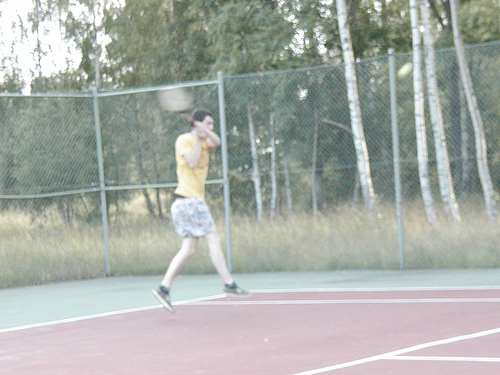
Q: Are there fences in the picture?
A: Yes, there is a fence.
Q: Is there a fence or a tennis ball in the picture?
A: Yes, there is a fence.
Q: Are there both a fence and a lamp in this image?
A: No, there is a fence but no lamps.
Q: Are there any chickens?
A: No, there are no chickens.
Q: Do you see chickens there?
A: No, there are no chickens.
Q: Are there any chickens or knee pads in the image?
A: No, there are no chickens or knee pads.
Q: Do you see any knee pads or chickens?
A: No, there are no chickens or knee pads.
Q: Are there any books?
A: No, there are no books.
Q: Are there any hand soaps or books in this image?
A: No, there are no books or hand soaps.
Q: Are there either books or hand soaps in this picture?
A: No, there are no books or hand soaps.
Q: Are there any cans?
A: No, there are no cans.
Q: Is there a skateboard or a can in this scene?
A: No, there are no cans or skateboards.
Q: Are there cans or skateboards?
A: No, there are no cans or skateboards.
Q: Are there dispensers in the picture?
A: No, there are no dispensers.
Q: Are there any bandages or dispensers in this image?
A: No, there are no dispensers or bandages.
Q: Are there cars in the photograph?
A: No, there are no cars.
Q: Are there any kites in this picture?
A: No, there are no kites.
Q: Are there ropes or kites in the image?
A: No, there are no kites or ropes.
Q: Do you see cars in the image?
A: No, there are no cars.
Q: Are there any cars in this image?
A: No, there are no cars.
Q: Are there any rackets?
A: Yes, there is a racket.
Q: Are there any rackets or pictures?
A: Yes, there is a racket.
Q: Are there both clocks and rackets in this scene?
A: No, there is a racket but no clocks.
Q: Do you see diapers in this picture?
A: No, there are no diapers.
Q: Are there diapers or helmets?
A: No, there are no diapers or helmets.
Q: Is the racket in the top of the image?
A: Yes, the racket is in the top of the image.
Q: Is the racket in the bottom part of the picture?
A: No, the racket is in the top of the image.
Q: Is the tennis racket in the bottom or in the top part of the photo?
A: The tennis racket is in the top of the image.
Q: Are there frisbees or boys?
A: No, there are no boys or frisbees.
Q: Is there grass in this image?
A: Yes, there is grass.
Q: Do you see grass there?
A: Yes, there is grass.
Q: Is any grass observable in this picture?
A: Yes, there is grass.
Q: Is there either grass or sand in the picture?
A: Yes, there is grass.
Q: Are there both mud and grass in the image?
A: No, there is grass but no mud.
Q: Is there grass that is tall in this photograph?
A: Yes, there is tall grass.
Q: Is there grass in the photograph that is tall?
A: Yes, there is grass that is tall.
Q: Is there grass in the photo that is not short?
A: Yes, there is tall grass.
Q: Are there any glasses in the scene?
A: No, there are no glasses.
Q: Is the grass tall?
A: Yes, the grass is tall.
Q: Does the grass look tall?
A: Yes, the grass is tall.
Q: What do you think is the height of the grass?
A: The grass is tall.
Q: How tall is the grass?
A: The grass is tall.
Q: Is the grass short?
A: No, the grass is tall.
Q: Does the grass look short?
A: No, the grass is tall.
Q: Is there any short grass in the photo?
A: No, there is grass but it is tall.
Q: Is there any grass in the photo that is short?
A: No, there is grass but it is tall.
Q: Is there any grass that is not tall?
A: No, there is grass but it is tall.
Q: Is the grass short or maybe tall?
A: The grass is tall.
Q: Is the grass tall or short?
A: The grass is tall.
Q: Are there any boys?
A: No, there are no boys.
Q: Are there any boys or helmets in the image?
A: No, there are no boys or helmets.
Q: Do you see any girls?
A: No, there are no girls.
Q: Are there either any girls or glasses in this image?
A: No, there are no girls or glasses.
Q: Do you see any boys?
A: No, there are no boys.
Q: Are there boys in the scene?
A: No, there are no boys.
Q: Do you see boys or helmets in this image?
A: No, there are no boys or helmets.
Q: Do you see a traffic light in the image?
A: No, there are no traffic lights.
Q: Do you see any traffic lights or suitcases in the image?
A: No, there are no traffic lights or suitcases.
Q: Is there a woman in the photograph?
A: No, there are no women.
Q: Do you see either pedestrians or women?
A: No, there are no women or pedestrians.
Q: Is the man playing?
A: Yes, the man is playing.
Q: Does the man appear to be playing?
A: Yes, the man is playing.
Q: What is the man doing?
A: The man is playing.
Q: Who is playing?
A: The man is playing.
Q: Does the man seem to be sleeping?
A: No, the man is playing.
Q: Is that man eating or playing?
A: The man is playing.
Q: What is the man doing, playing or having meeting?
A: The man is playing.